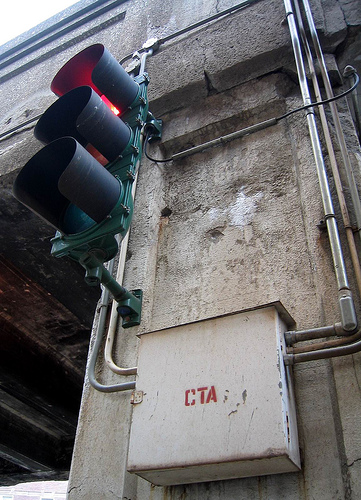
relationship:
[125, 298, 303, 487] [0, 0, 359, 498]
box on building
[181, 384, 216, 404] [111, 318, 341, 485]
cta on box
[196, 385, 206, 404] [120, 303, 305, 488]
t on box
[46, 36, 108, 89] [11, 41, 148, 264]
light on top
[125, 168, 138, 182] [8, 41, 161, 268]
bolt on side of light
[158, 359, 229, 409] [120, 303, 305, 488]
cta written on box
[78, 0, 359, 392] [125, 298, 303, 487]
pipes running from box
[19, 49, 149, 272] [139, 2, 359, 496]
light attached to wall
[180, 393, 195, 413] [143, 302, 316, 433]
letter on electrical box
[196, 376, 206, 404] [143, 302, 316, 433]
letter on electrical box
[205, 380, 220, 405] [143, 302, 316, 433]
letter on electrical box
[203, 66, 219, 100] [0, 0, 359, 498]
crack on building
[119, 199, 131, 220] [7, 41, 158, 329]
bolt on light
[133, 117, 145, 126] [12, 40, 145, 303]
bolt on light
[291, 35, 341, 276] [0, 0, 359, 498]
rods attached to building